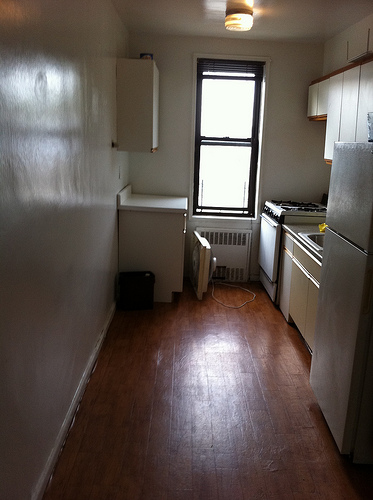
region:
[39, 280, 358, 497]
A brown wooden floor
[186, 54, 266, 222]
Daylight coming from a window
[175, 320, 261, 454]
A light glare on the floor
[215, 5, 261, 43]
A light on the ceiling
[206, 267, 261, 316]
A white electrical wire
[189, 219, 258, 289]
A radiator against the wall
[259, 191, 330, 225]
Black burners on a stove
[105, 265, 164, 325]
A black trash bin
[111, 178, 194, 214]
The countertop is white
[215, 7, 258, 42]
A light is turned on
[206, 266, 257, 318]
wire from the fan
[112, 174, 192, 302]
counter in the kitchen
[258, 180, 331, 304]
white stove in the kitchen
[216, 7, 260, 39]
Light in the ceiling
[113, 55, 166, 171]
cabinet above the counter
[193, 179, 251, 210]
children guard on a window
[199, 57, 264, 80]
blinds on a window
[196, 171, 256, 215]
window with black frames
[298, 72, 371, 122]
brown borders on a cabinet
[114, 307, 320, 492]
a brown wooden floor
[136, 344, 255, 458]
a brown wooden floor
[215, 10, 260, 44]
the light is yellow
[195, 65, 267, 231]
brown frame around window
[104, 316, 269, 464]
brown and wooden floor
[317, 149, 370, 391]
white fridge in kitchen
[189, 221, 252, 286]
white radiator under window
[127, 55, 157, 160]
white cabinet near window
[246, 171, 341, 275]
white range near window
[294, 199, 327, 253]
grey sink near range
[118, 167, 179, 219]
white counter near window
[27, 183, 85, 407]
white wall in kitchen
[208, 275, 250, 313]
white cord on floor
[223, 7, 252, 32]
the light is on the ceiling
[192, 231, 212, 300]
a window fan is on the floor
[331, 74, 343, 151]
a white cabinet door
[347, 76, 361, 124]
a white cabinet door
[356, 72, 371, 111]
a white cabinet door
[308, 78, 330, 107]
a white cabinet door